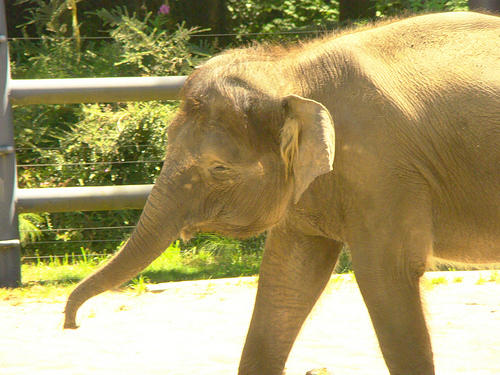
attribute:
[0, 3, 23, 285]
pole — metal, thick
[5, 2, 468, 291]
green area — lush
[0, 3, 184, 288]
fence — silver, metal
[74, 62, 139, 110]
pole — metal, grey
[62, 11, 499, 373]
elephant — brown, large, facing left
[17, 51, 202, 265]
bush — green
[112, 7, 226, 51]
flower — purple